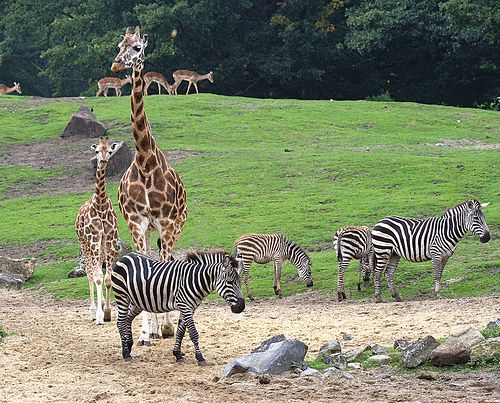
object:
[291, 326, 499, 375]
grass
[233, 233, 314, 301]
smallest zebra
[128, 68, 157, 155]
neck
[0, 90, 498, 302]
grass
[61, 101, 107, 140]
rock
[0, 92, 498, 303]
hill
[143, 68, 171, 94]
deer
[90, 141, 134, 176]
rock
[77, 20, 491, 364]
animals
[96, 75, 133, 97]
deer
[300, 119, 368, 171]
wall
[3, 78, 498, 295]
pretty green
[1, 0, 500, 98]
trees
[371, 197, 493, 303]
zebra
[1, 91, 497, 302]
field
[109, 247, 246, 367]
zebra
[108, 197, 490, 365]
zebras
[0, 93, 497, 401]
ground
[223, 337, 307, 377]
rock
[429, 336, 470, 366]
rock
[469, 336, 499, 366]
rock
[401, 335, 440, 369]
rock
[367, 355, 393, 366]
rock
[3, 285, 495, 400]
dirt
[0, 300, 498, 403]
dirt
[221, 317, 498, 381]
pile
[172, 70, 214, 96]
deer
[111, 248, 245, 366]
walking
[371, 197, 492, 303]
walking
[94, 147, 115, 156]
looking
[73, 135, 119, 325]
baby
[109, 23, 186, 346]
adult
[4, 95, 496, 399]
clearing